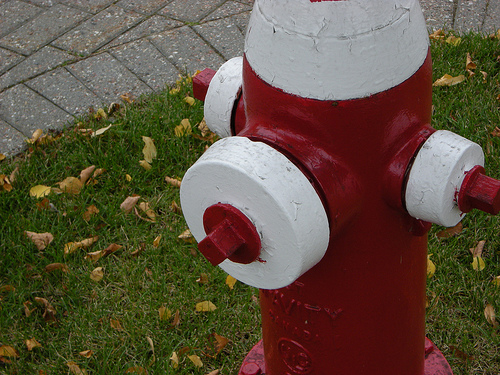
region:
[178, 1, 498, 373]
A red and white fire hydrant.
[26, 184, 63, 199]
A yellow leaf.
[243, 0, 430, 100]
A white top of a fire hydrant.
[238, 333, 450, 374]
A circular base of a fire hydrant.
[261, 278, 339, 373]
A sign on a fire dydrant.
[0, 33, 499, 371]
Green grass around a fire hydrant.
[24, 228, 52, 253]
A brown leaf in a grass.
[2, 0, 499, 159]
A paved surface.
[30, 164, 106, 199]
Leaves in a grass.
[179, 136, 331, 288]
A side parts of a fire hydrant.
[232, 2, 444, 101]
The top is white.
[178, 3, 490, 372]
The fire hydrand is red and white.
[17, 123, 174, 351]
The leaves are yellow.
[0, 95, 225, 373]
The grass is green.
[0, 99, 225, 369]
The grass is tall.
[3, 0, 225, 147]
The sidewalk is brick.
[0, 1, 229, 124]
The sidewalk is gray.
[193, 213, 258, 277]
The bolt is red.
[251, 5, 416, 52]
The paint is cracked.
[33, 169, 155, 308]
Greem littered grass field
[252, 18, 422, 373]
A short metalic pole with red and white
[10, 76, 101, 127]
A grey stole tile road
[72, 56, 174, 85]
A grey stole tile road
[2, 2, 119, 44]
A grey stole tile road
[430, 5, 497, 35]
A grey stole tile road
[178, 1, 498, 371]
a red and white fire hydrant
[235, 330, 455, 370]
a red fire hydrant base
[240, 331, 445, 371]
two red hex bolts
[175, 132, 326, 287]
left white metal base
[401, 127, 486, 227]
right white metal base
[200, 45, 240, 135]
white metal base facing curve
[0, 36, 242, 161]
gray and white side walk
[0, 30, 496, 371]
area of green grass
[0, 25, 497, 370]
yellow and brown leaves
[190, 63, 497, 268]
three red hex bolt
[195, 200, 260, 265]
front fire fire hydrant bolt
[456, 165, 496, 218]
right fire fire hydrant bolt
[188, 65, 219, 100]
left fire fire hydrant bolt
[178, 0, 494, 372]
fire hydrant beside curve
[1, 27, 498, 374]
yellow and brown leaves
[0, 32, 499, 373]
green grass near side walk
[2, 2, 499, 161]
gray block side walk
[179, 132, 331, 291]
front fire hydrant water valve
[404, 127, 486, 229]
right fire hydrant water valve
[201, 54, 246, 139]
left fire hydrant water valve